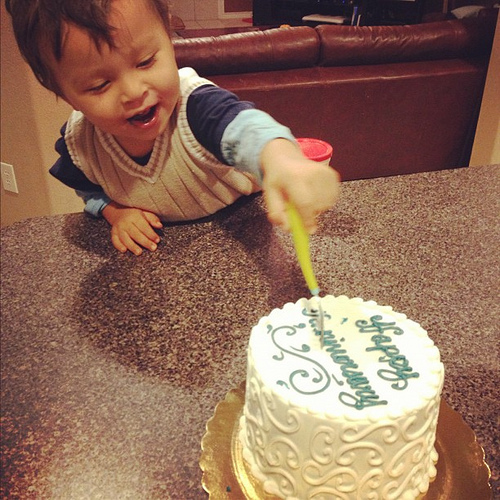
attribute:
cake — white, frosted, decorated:
[231, 293, 447, 500]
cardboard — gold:
[196, 375, 493, 498]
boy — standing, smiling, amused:
[4, 1, 341, 257]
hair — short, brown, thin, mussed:
[8, 2, 176, 104]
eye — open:
[135, 47, 158, 70]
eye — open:
[82, 75, 111, 96]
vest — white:
[64, 68, 259, 221]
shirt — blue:
[66, 64, 305, 217]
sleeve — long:
[190, 84, 301, 183]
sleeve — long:
[55, 135, 119, 221]